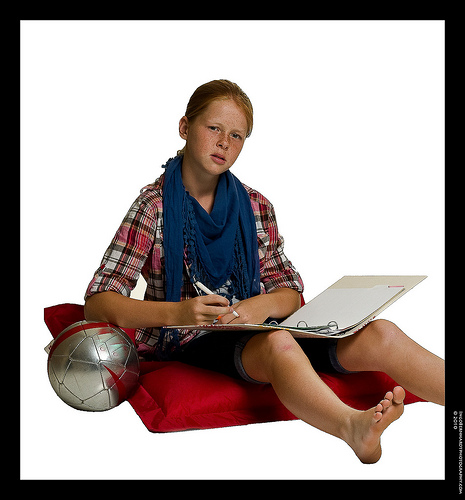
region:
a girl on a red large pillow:
[33, 59, 438, 469]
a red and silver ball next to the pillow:
[45, 319, 139, 410]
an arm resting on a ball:
[79, 287, 162, 329]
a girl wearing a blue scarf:
[110, 63, 296, 292]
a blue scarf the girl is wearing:
[159, 168, 224, 281]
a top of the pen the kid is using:
[193, 279, 204, 293]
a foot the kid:
[339, 379, 420, 470]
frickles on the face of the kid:
[196, 135, 214, 148]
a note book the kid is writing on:
[171, 271, 432, 342]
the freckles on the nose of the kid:
[222, 135, 229, 144]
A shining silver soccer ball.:
[47, 326, 149, 413]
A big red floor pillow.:
[61, 296, 445, 428]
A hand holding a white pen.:
[197, 271, 242, 325]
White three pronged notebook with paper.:
[175, 273, 434, 335]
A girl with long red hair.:
[177, 78, 256, 175]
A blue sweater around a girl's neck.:
[162, 141, 258, 301]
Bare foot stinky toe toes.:
[355, 384, 407, 461]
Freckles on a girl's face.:
[194, 132, 211, 158]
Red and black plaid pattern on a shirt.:
[134, 209, 158, 252]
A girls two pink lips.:
[204, 151, 233, 166]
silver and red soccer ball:
[54, 321, 135, 410]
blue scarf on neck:
[163, 158, 258, 304]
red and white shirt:
[93, 185, 304, 334]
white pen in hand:
[192, 279, 243, 316]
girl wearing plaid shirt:
[98, 83, 305, 351]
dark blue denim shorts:
[182, 330, 343, 385]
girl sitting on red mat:
[76, 79, 444, 468]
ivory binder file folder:
[167, 275, 421, 338]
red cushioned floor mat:
[45, 302, 434, 428]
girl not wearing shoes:
[99, 79, 447, 462]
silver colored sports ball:
[36, 319, 155, 413]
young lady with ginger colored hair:
[103, 71, 322, 304]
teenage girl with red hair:
[95, 66, 354, 300]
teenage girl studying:
[134, 64, 296, 204]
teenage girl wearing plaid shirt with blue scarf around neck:
[81, 64, 345, 354]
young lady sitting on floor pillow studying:
[55, 71, 446, 465]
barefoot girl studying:
[53, 77, 446, 475]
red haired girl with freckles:
[150, 76, 289, 185]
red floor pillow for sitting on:
[28, 295, 427, 432]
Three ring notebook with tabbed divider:
[156, 272, 440, 341]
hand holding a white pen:
[180, 277, 243, 320]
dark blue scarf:
[156, 163, 270, 295]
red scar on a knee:
[271, 337, 306, 357]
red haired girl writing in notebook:
[83, 74, 431, 333]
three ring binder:
[164, 269, 429, 344]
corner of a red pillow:
[132, 382, 246, 439]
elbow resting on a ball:
[78, 273, 141, 334]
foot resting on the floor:
[337, 374, 417, 467]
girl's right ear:
[169, 114, 196, 145]